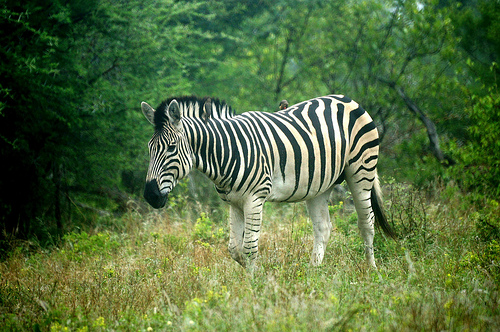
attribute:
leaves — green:
[125, 30, 206, 89]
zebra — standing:
[139, 95, 396, 268]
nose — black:
[144, 180, 169, 207]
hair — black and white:
[153, 96, 239, 128]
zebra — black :
[136, 88, 407, 273]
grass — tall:
[0, 183, 498, 328]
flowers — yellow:
[200, 288, 215, 303]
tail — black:
[367, 175, 406, 253]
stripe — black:
[320, 92, 337, 186]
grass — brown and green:
[6, 257, 497, 330]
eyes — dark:
[163, 140, 185, 167]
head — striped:
[139, 65, 201, 214]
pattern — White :
[264, 125, 322, 149]